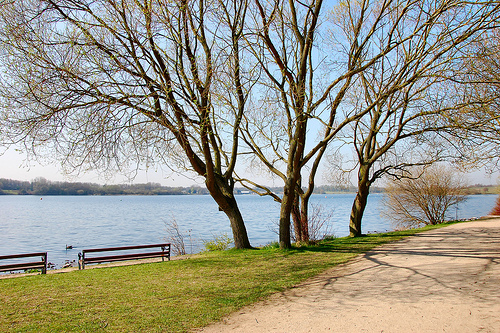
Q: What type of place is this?
A: It is a lake.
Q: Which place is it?
A: It is a lake.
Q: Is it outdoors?
A: Yes, it is outdoors.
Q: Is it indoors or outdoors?
A: It is outdoors.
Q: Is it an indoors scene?
A: No, it is outdoors.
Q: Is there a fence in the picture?
A: No, there are no fences.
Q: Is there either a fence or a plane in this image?
A: No, there are no fences or airplanes.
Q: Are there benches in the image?
A: Yes, there is a bench.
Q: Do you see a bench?
A: Yes, there is a bench.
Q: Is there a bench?
A: Yes, there is a bench.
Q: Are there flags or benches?
A: Yes, there is a bench.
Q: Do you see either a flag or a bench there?
A: Yes, there is a bench.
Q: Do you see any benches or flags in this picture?
A: Yes, there is a bench.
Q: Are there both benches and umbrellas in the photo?
A: No, there is a bench but no umbrellas.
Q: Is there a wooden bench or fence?
A: Yes, there is a wood bench.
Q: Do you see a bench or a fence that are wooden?
A: Yes, the bench is wooden.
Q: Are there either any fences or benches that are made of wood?
A: Yes, the bench is made of wood.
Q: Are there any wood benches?
A: Yes, there is a wood bench.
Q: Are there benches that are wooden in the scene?
A: Yes, there is a wood bench.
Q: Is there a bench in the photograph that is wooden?
A: Yes, there is a bench that is wooden.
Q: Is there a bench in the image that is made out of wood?
A: Yes, there is a bench that is made of wood.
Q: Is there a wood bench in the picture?
A: Yes, there is a bench that is made of wood.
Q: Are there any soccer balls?
A: No, there are no soccer balls.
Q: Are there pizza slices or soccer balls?
A: No, there are no soccer balls or pizza slices.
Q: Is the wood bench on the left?
A: Yes, the bench is on the left of the image.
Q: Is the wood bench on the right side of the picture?
A: No, the bench is on the left of the image.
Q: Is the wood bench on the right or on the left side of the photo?
A: The bench is on the left of the image.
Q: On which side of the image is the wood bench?
A: The bench is on the left of the image.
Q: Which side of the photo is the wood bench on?
A: The bench is on the left of the image.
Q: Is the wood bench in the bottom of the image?
A: Yes, the bench is in the bottom of the image.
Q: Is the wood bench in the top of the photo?
A: No, the bench is in the bottom of the image.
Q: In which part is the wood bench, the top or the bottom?
A: The bench is in the bottom of the image.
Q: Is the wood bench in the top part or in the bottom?
A: The bench is in the bottom of the image.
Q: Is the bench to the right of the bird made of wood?
A: Yes, the bench is made of wood.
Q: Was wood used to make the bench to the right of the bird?
A: Yes, the bench is made of wood.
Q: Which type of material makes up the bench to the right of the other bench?
A: The bench is made of wood.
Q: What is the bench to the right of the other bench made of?
A: The bench is made of wood.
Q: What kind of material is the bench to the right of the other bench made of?
A: The bench is made of wood.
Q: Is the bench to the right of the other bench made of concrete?
A: No, the bench is made of wood.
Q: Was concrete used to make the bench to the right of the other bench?
A: No, the bench is made of wood.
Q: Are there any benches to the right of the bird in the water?
A: Yes, there is a bench to the right of the bird.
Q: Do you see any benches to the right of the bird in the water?
A: Yes, there is a bench to the right of the bird.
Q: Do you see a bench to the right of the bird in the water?
A: Yes, there is a bench to the right of the bird.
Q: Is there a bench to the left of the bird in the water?
A: No, the bench is to the right of the bird.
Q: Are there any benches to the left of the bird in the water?
A: No, the bench is to the right of the bird.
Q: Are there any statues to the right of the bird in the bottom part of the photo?
A: No, there is a bench to the right of the bird.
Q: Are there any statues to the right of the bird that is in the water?
A: No, there is a bench to the right of the bird.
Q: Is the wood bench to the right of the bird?
A: Yes, the bench is to the right of the bird.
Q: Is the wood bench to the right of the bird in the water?
A: Yes, the bench is to the right of the bird.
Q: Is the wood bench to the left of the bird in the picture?
A: No, the bench is to the right of the bird.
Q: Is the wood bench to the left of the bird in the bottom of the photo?
A: No, the bench is to the right of the bird.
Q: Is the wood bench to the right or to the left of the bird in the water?
A: The bench is to the right of the bird.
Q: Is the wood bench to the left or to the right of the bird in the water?
A: The bench is to the right of the bird.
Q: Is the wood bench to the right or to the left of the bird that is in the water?
A: The bench is to the right of the bird.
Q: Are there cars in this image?
A: No, there are no cars.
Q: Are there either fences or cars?
A: No, there are no cars or fences.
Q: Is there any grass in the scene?
A: Yes, there is grass.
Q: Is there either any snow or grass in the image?
A: Yes, there is grass.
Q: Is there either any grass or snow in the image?
A: Yes, there is grass.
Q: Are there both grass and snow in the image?
A: No, there is grass but no snow.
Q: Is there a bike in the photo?
A: No, there are no bikes.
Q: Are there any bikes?
A: No, there are no bikes.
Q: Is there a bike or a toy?
A: No, there are no bikes or toys.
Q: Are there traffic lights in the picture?
A: No, there are no traffic lights.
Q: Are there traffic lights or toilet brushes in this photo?
A: No, there are no traffic lights or toilet brushes.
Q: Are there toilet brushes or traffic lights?
A: No, there are no traffic lights or toilet brushes.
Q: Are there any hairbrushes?
A: No, there are no hairbrushes.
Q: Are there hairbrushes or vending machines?
A: No, there are no hairbrushes or vending machines.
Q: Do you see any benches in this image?
A: Yes, there is a bench.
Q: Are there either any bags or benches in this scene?
A: Yes, there is a bench.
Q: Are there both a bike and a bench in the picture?
A: No, there is a bench but no bikes.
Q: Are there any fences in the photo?
A: No, there are no fences.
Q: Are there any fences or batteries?
A: No, there are no fences or batteries.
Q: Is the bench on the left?
A: Yes, the bench is on the left of the image.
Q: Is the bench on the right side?
A: No, the bench is on the left of the image.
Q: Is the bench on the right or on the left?
A: The bench is on the left of the image.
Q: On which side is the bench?
A: The bench is on the left of the image.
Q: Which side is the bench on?
A: The bench is on the left of the image.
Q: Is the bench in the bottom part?
A: Yes, the bench is in the bottom of the image.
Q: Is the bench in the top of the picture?
A: No, the bench is in the bottom of the image.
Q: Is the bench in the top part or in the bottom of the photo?
A: The bench is in the bottom of the image.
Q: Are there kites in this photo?
A: No, there are no kites.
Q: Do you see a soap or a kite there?
A: No, there are no kites or soaps.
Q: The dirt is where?
A: The dirt is in the grass.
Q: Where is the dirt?
A: The dirt is in the grass.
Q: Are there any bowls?
A: No, there are no bowls.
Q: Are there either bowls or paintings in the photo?
A: No, there are no bowls or paintings.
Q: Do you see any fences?
A: No, there are no fences.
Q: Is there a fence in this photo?
A: No, there are no fences.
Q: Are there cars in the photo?
A: No, there are no cars.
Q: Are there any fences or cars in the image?
A: No, there are no cars or fences.